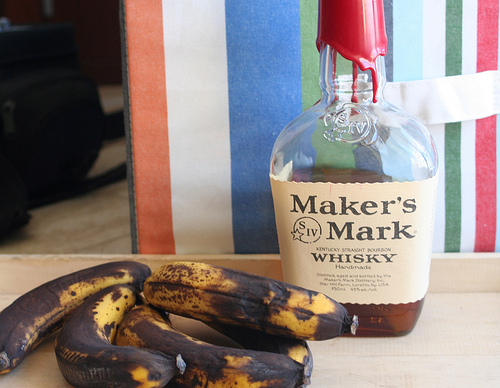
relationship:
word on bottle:
[301, 243, 415, 273] [259, 32, 438, 342]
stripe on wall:
[230, 17, 300, 259] [122, 5, 497, 263]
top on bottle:
[314, 0, 389, 72] [259, 32, 438, 342]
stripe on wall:
[171, 6, 232, 267] [122, 5, 497, 263]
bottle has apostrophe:
[259, 32, 438, 342] [396, 186, 404, 209]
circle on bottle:
[324, 109, 375, 147] [259, 32, 438, 342]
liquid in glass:
[327, 290, 428, 324] [249, 142, 430, 314]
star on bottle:
[288, 225, 304, 242] [259, 32, 438, 342]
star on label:
[288, 225, 304, 242] [277, 192, 421, 296]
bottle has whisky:
[259, 32, 438, 342] [327, 292, 416, 338]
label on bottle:
[277, 192, 421, 296] [259, 32, 438, 342]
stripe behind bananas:
[121, 8, 177, 254] [55, 265, 314, 379]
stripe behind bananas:
[230, 17, 300, 259] [55, 265, 314, 379]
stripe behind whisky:
[230, 17, 300, 259] [327, 292, 416, 338]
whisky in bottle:
[327, 292, 416, 338] [259, 32, 438, 342]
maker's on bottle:
[285, 188, 417, 219] [259, 32, 438, 342]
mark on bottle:
[328, 217, 414, 245] [259, 32, 438, 342]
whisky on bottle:
[308, 246, 403, 265] [259, 32, 438, 342]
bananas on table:
[55, 265, 314, 379] [95, 258, 474, 383]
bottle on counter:
[259, 32, 438, 342] [263, 259, 490, 383]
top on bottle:
[320, 6, 384, 51] [259, 32, 438, 342]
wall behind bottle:
[122, 5, 497, 263] [259, 32, 438, 342]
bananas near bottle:
[55, 265, 314, 379] [259, 32, 438, 342]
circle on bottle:
[321, 103, 374, 148] [259, 32, 438, 342]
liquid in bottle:
[327, 302, 424, 338] [259, 32, 438, 342]